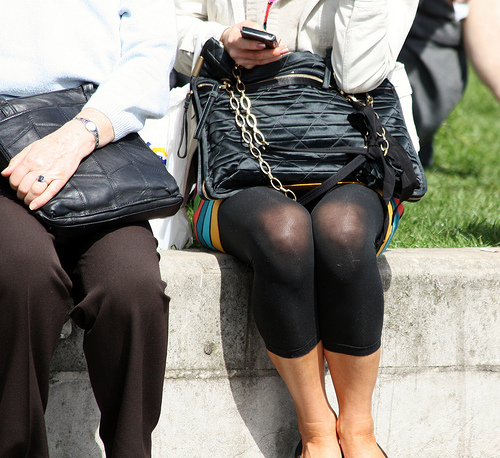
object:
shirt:
[150, 2, 421, 252]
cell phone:
[240, 24, 281, 50]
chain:
[220, 73, 390, 202]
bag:
[178, 50, 429, 203]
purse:
[0, 83, 184, 244]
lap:
[0, 216, 172, 343]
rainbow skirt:
[192, 187, 406, 259]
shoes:
[293, 439, 387, 457]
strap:
[201, 36, 332, 88]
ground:
[386, 65, 499, 247]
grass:
[381, 71, 499, 247]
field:
[385, 62, 500, 247]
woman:
[0, 0, 179, 457]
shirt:
[0, 0, 179, 143]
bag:
[178, 39, 447, 227]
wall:
[5, 246, 500, 458]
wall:
[413, 265, 492, 386]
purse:
[176, 37, 428, 200]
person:
[153, 0, 424, 458]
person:
[0, 0, 179, 458]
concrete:
[0, 245, 500, 458]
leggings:
[219, 186, 386, 358]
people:
[0, 0, 500, 458]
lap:
[227, 189, 384, 313]